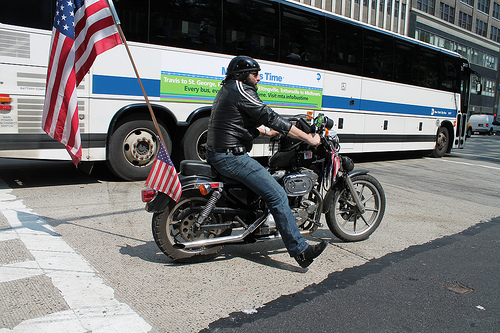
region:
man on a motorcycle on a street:
[29, 4, 409, 264]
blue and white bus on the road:
[7, 4, 499, 186]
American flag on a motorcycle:
[136, 134, 194, 206]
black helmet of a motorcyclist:
[215, 47, 267, 79]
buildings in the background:
[370, 3, 498, 43]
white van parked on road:
[462, 112, 497, 139]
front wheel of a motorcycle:
[327, 171, 387, 246]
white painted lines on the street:
[0, 183, 141, 331]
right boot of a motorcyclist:
[286, 237, 339, 277]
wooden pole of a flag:
[119, 45, 172, 153]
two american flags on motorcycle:
[36, 2, 220, 279]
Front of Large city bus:
[329, 10, 486, 171]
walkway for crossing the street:
[0, 179, 155, 331]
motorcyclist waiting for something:
[198, 43, 327, 279]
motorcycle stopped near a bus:
[137, 95, 406, 295]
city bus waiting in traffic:
[410, 3, 497, 205]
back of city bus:
[1, 8, 148, 238]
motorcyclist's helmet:
[213, 49, 270, 101]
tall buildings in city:
[410, 1, 496, 112]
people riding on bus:
[194, 4, 468, 82]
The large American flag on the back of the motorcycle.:
[36, 0, 123, 166]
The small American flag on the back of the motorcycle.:
[143, 125, 183, 202]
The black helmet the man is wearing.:
[222, 48, 262, 76]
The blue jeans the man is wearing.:
[221, 153, 312, 252]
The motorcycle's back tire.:
[151, 196, 238, 265]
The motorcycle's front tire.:
[322, 172, 390, 239]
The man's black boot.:
[291, 240, 329, 265]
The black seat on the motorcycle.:
[179, 155, 226, 174]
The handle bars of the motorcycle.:
[280, 106, 330, 152]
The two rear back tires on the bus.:
[105, 105, 231, 180]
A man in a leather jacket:
[146, 55, 387, 266]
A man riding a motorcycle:
[147, 49, 384, 267]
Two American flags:
[41, 0, 182, 222]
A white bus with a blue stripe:
[342, 32, 477, 157]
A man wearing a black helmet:
[208, 57, 278, 118]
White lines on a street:
[1, 195, 131, 330]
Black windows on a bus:
[174, 7, 324, 49]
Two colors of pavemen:
[428, 207, 498, 267]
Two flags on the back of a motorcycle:
[46, 5, 381, 255]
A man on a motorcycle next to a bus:
[101, 27, 406, 283]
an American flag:
[35, 0, 154, 166]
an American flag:
[142, 132, 186, 207]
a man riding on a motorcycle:
[134, 47, 394, 272]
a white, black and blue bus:
[3, 0, 471, 186]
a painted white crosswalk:
[0, 171, 155, 329]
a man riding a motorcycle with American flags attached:
[21, 0, 391, 271]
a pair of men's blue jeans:
[199, 140, 309, 264]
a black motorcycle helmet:
[219, 53, 261, 77]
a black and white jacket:
[204, 77, 293, 153]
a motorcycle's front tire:
[323, 165, 388, 245]